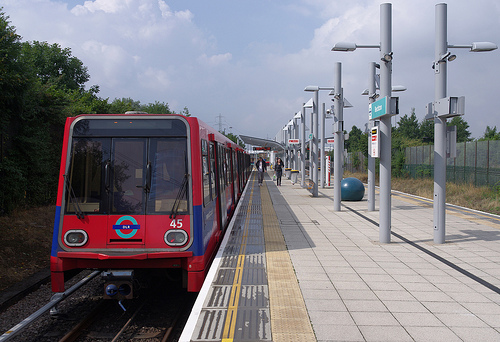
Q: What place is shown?
A: It is a sidewalk.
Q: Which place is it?
A: It is a sidewalk.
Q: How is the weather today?
A: It is sunny.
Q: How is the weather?
A: It is sunny.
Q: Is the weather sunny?
A: Yes, it is sunny.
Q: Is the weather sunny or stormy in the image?
A: It is sunny.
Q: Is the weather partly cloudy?
A: No, it is sunny.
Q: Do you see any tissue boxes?
A: No, there are no tissue boxes.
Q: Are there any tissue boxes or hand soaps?
A: No, there are no tissue boxes or hand soaps.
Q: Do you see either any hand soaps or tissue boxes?
A: No, there are no tissue boxes or hand soaps.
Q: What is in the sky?
A: The clouds are in the sky.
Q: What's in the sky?
A: The clouds are in the sky.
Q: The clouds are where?
A: The clouds are in the sky.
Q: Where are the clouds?
A: The clouds are in the sky.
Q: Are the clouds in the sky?
A: Yes, the clouds are in the sky.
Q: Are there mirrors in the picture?
A: No, there are no mirrors.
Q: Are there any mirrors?
A: No, there are no mirrors.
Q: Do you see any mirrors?
A: No, there are no mirrors.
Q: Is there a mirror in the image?
A: No, there are no mirrors.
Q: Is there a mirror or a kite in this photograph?
A: No, there are no mirrors or kites.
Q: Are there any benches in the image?
A: No, there are no benches.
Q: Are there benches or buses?
A: No, there are no benches or buses.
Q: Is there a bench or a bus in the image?
A: No, there are no benches or buses.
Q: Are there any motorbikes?
A: No, there are no motorbikes.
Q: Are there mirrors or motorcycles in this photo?
A: No, there are no motorcycles or mirrors.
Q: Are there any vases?
A: No, there are no vases.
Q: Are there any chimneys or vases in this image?
A: No, there are no vases or chimneys.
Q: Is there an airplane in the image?
A: No, there are no airplanes.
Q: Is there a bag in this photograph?
A: No, there are no bags.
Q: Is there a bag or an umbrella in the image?
A: No, there are no bags or umbrellas.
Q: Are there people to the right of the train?
A: Yes, there are people to the right of the train.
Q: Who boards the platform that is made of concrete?
A: The people board the platform.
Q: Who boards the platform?
A: The people board the platform.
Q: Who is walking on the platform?
A: The people are walking on the platform.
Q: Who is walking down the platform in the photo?
A: The people are walking down the platform.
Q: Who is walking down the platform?
A: The people are walking down the platform.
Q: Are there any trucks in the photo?
A: No, there are no trucks.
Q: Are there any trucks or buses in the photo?
A: No, there are no trucks or buses.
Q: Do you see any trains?
A: Yes, there is a train.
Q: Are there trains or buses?
A: Yes, there is a train.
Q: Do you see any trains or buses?
A: Yes, there is a train.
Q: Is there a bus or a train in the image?
A: Yes, there is a train.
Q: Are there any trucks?
A: No, there are no trucks.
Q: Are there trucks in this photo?
A: No, there are no trucks.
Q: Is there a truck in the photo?
A: No, there are no trucks.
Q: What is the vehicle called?
A: The vehicle is a train.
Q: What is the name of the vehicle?
A: The vehicle is a train.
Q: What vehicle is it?
A: The vehicle is a train.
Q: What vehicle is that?
A: This is a train.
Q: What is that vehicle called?
A: This is a train.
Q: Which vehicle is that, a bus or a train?
A: This is a train.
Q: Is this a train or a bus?
A: This is a train.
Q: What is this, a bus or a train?
A: This is a train.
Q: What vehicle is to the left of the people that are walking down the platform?
A: The vehicle is a train.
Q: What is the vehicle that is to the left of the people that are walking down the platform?
A: The vehicle is a train.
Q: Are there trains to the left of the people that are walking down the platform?
A: Yes, there is a train to the left of the people.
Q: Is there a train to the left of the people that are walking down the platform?
A: Yes, there is a train to the left of the people.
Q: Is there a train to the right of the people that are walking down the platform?
A: No, the train is to the left of the people.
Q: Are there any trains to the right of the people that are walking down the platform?
A: No, the train is to the left of the people.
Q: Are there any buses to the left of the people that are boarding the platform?
A: No, there is a train to the left of the people.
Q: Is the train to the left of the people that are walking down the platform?
A: Yes, the train is to the left of the people.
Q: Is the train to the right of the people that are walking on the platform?
A: No, the train is to the left of the people.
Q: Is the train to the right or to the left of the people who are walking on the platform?
A: The train is to the left of the people.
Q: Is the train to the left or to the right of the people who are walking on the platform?
A: The train is to the left of the people.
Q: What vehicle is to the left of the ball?
A: The vehicle is a train.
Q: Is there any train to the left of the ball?
A: Yes, there is a train to the left of the ball.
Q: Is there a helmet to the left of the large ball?
A: No, there is a train to the left of the ball.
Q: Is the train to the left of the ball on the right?
A: Yes, the train is to the left of the ball.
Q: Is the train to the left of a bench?
A: No, the train is to the left of the ball.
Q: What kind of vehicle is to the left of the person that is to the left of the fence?
A: The vehicle is a train.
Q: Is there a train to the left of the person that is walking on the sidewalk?
A: Yes, there is a train to the left of the person.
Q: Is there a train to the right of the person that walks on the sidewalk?
A: No, the train is to the left of the person.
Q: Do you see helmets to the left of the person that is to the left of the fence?
A: No, there is a train to the left of the person.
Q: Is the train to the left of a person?
A: Yes, the train is to the left of a person.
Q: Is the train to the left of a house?
A: No, the train is to the left of a person.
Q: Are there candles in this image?
A: No, there are no candles.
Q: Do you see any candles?
A: No, there are no candles.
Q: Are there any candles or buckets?
A: No, there are no candles or buckets.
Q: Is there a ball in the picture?
A: Yes, there is a ball.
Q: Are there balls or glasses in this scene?
A: Yes, there is a ball.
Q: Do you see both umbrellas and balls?
A: No, there is a ball but no umbrellas.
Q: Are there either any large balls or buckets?
A: Yes, there is a large ball.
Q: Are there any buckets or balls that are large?
A: Yes, the ball is large.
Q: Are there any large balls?
A: Yes, there is a large ball.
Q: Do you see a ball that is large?
A: Yes, there is a ball that is large.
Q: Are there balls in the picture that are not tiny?
A: Yes, there is a large ball.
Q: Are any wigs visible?
A: No, there are no wigs.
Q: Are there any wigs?
A: No, there are no wigs.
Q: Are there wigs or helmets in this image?
A: No, there are no wigs or helmets.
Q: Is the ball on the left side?
A: No, the ball is on the right of the image.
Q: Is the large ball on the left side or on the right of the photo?
A: The ball is on the right of the image.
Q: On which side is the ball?
A: The ball is on the right of the image.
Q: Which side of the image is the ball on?
A: The ball is on the right of the image.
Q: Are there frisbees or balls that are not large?
A: No, there is a ball but it is large.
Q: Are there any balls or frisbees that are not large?
A: No, there is a ball but it is large.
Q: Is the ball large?
A: Yes, the ball is large.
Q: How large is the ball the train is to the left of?
A: The ball is large.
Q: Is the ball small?
A: No, the ball is large.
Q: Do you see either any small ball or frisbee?
A: No, there is a ball but it is large.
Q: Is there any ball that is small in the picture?
A: No, there is a ball but it is large.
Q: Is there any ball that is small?
A: No, there is a ball but it is large.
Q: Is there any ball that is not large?
A: No, there is a ball but it is large.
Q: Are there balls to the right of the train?
A: Yes, there is a ball to the right of the train.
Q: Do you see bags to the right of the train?
A: No, there is a ball to the right of the train.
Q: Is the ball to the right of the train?
A: Yes, the ball is to the right of the train.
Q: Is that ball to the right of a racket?
A: No, the ball is to the right of the train.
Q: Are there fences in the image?
A: Yes, there is a fence.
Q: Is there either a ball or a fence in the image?
A: Yes, there is a fence.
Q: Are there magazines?
A: No, there are no magazines.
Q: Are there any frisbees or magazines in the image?
A: No, there are no magazines or frisbees.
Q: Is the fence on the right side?
A: Yes, the fence is on the right of the image.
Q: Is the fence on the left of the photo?
A: No, the fence is on the right of the image.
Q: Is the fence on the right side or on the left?
A: The fence is on the right of the image.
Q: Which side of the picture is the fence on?
A: The fence is on the right of the image.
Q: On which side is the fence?
A: The fence is on the right of the image.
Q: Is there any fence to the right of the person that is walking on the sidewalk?
A: Yes, there is a fence to the right of the person.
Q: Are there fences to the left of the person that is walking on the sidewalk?
A: No, the fence is to the right of the person.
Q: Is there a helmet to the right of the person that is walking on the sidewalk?
A: No, there is a fence to the right of the person.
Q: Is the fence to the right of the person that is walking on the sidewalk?
A: Yes, the fence is to the right of the person.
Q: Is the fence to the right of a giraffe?
A: No, the fence is to the right of the person.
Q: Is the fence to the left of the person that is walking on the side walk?
A: No, the fence is to the right of the person.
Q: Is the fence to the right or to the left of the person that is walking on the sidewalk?
A: The fence is to the right of the person.